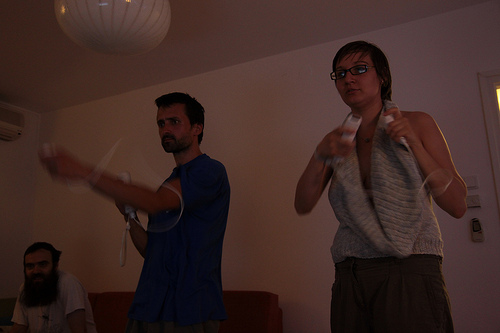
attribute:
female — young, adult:
[289, 37, 466, 332]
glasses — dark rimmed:
[325, 57, 384, 83]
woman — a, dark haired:
[293, 39, 468, 331]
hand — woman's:
[384, 111, 416, 148]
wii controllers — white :
[22, 140, 153, 220]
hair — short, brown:
[332, 40, 392, 96]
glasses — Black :
[329, 64, 380, 78]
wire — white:
[411, 168, 456, 204]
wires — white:
[326, 150, 453, 213]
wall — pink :
[39, 0, 499, 327]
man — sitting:
[9, 241, 93, 332]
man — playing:
[32, 89, 237, 331]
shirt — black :
[149, 160, 227, 310]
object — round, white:
[52, 1, 172, 54]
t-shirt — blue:
[127, 153, 229, 331]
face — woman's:
[337, 53, 384, 106]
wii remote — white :
[341, 107, 363, 146]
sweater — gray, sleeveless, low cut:
[328, 100, 445, 260]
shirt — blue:
[128, 152, 230, 325]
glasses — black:
[329, 63, 381, 81]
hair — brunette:
[332, 40, 393, 108]